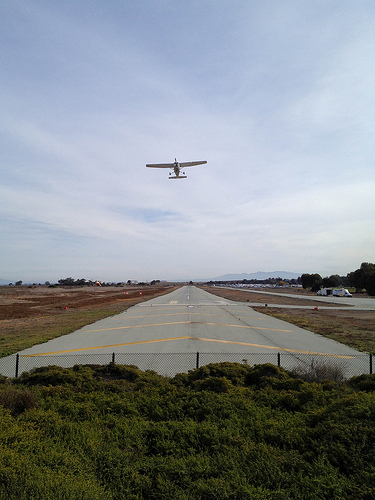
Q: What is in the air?
A: A plane.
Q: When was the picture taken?
A: Daytime.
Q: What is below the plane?
A: The runway.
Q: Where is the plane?
A: The air.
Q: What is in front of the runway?
A: Trees.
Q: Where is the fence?
A: Between the runway and trees.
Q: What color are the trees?
A: Green.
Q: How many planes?
A: One.